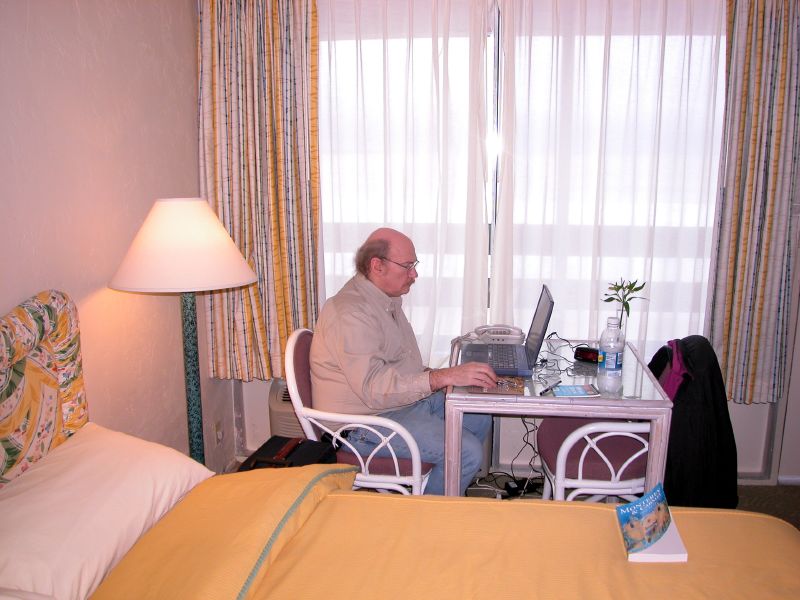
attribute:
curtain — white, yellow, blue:
[694, 7, 795, 409]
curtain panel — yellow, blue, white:
[185, 1, 331, 386]